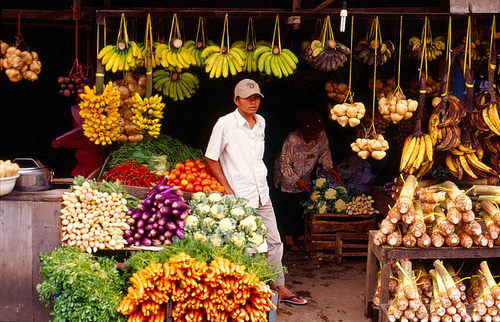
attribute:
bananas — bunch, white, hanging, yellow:
[98, 39, 143, 72]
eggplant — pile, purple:
[124, 189, 189, 251]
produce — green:
[37, 136, 291, 321]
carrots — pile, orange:
[115, 240, 289, 321]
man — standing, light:
[205, 79, 307, 308]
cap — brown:
[233, 77, 265, 100]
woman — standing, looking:
[273, 109, 343, 252]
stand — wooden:
[365, 234, 498, 321]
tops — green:
[122, 237, 281, 282]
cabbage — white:
[182, 190, 265, 259]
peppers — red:
[101, 156, 165, 188]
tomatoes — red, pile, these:
[166, 157, 227, 194]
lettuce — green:
[33, 249, 125, 320]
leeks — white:
[346, 194, 383, 215]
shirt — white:
[203, 109, 270, 210]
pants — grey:
[243, 199, 286, 289]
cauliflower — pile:
[308, 180, 348, 215]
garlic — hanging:
[2, 40, 43, 82]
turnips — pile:
[370, 178, 499, 249]